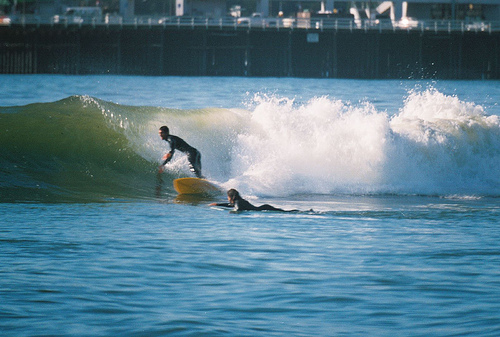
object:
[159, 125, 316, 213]
two people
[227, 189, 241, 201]
hair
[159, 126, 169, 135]
hair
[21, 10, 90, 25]
airplane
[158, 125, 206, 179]
guy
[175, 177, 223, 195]
pole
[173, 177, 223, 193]
surfboard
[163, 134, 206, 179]
suit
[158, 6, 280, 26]
traffic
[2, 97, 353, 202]
large seawall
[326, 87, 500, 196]
stone ledge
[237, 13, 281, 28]
van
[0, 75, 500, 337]
water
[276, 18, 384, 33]
fence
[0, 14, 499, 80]
bridge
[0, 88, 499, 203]
wave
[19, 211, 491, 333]
ocean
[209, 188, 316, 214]
people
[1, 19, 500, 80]
board walk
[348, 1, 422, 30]
airplane